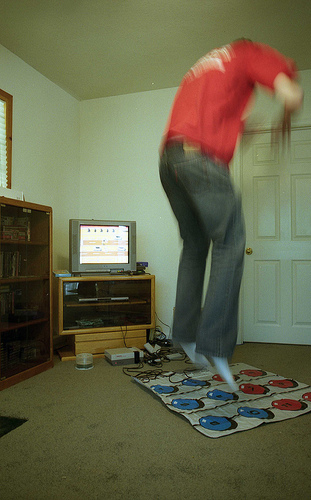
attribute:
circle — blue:
[199, 414, 233, 432]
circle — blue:
[236, 404, 269, 418]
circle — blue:
[171, 395, 200, 411]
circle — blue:
[206, 386, 235, 402]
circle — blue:
[149, 382, 175, 397]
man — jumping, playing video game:
[153, 36, 304, 395]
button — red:
[272, 395, 304, 413]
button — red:
[239, 382, 268, 398]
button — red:
[269, 377, 295, 388]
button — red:
[242, 368, 265, 378]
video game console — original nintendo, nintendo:
[105, 345, 144, 364]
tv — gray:
[69, 218, 136, 273]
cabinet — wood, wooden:
[56, 270, 155, 360]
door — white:
[235, 119, 310, 348]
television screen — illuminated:
[78, 225, 127, 263]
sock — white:
[205, 359, 241, 394]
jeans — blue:
[159, 143, 247, 358]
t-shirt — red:
[157, 40, 296, 164]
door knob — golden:
[245, 245, 255, 258]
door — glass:
[62, 283, 151, 328]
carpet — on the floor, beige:
[0, 336, 310, 499]